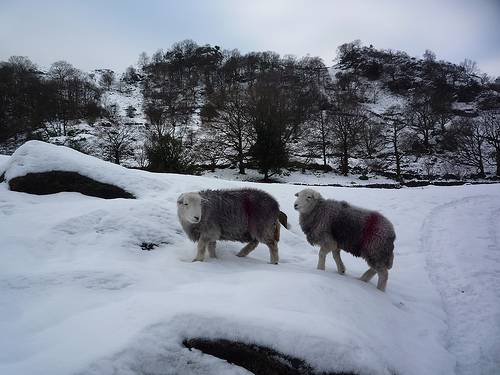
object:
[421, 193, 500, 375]
tracks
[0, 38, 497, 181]
trees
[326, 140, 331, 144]
person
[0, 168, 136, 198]
rock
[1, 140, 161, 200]
rock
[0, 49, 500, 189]
mountain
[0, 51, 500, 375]
snow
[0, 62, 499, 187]
hillside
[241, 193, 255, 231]
spot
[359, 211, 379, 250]
marker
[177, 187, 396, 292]
sheep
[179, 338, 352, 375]
wedge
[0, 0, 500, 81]
sky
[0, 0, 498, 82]
clouds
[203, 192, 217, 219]
shoulder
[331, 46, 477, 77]
mountain top